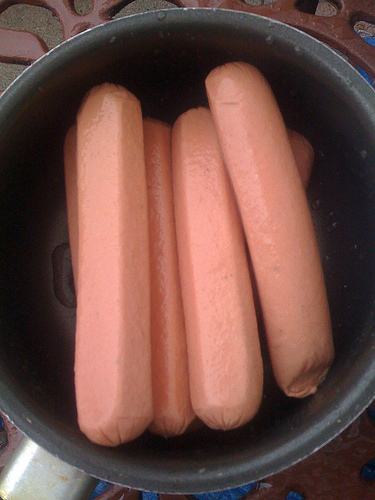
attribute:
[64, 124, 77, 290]
sausage — pink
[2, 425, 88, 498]
handle — silver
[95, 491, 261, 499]
flame — blue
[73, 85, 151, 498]
sausage — pink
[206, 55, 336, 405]
sausage — pink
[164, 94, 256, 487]
sausage — pink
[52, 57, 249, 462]
sausages — raw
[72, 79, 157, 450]
sausage — pink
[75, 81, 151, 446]
hotdog — big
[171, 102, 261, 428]
hotdog — big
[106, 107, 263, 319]
hotdogs — pink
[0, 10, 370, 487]
pan — grey, black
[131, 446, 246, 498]
bowl — black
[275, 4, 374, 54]
stove — grey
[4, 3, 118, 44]
stove — grey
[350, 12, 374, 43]
plastichole — pink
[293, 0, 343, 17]
plastichole — pink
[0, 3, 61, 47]
plastichole — pink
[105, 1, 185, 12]
plastichole — pink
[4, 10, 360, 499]
pot — grey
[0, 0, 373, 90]
stove — red, metal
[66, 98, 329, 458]
sausage — pink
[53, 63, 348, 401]
sausage — pink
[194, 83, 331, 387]
sausage — pink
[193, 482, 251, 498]
flame — blue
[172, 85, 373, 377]
sausage — pink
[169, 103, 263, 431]
wiener — pink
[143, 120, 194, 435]
sausage — pink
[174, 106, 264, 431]
sausage — pink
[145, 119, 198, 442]
sausage — pink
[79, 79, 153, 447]
sausage — pink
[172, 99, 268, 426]
hot dog — pink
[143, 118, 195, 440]
hot dog — pink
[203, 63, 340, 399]
hot dog — pink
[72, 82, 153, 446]
hot dog — pink